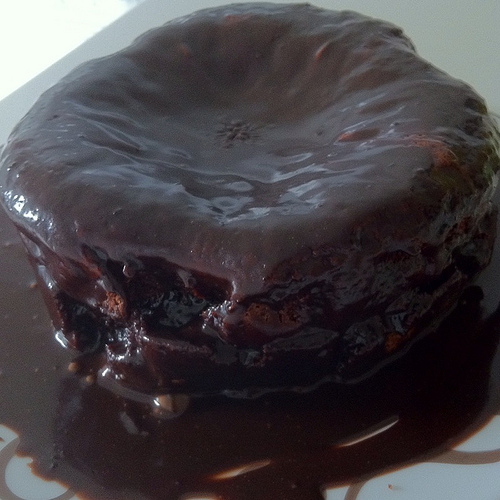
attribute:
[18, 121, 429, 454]
cake — chocolate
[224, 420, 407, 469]
plate — white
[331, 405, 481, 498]
line — brown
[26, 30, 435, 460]
dessert cake — chocolate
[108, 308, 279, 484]
sauce — white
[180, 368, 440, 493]
plate — white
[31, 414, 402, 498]
sauce — chocolate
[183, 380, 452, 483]
plate — white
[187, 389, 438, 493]
plate — white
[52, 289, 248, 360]
pastry crumb — chocolate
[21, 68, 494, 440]
cake — chocolate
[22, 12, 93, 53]
background — white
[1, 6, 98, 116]
table — white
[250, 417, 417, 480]
plate — white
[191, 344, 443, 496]
sauce — chocolate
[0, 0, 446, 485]
cake — chocolate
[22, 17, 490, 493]
dessert — chocolate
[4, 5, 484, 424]
chocolate desert — small, bake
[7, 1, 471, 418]
desert — with chocolate frosting, with syrup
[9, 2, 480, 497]
desert — with syrup, with chocolate glaze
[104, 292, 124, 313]
light brown/part — of dessert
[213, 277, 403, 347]
dark brown/edge — of dessert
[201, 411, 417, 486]
plate — white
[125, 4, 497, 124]
corner — shadowed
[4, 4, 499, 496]
plate — white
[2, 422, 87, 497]
circle — brown